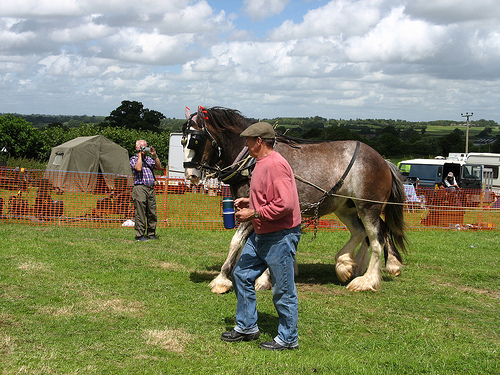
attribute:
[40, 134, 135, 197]
tent — green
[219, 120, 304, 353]
man — older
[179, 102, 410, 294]
horse — clydesdale, big, brown, white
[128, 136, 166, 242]
man — taking pictures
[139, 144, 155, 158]
video camera — gray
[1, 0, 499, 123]
sky — cloudy, cloudy blue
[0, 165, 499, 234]
fencing — orange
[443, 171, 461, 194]
man — sitting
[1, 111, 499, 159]
landscape — hilly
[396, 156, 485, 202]
van — blue